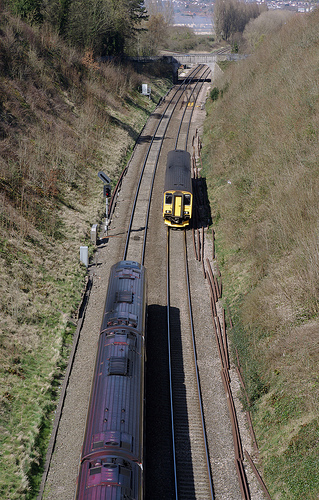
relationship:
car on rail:
[162, 149, 194, 230] [40, 63, 215, 497]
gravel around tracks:
[199, 246, 214, 274] [169, 223, 202, 322]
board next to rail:
[200, 228, 233, 305] [40, 63, 215, 497]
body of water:
[174, 8, 204, 29] [192, 8, 221, 29]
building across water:
[173, 10, 290, 69] [192, 8, 221, 29]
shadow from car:
[207, 185, 218, 217] [162, 149, 194, 230]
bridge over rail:
[169, 12, 275, 99] [40, 63, 215, 497]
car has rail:
[162, 149, 194, 230] [40, 63, 215, 497]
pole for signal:
[90, 180, 119, 242] [101, 176, 122, 243]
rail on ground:
[134, 258, 203, 393] [177, 236, 198, 343]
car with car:
[162, 149, 194, 230] [77, 326, 158, 461]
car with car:
[162, 149, 194, 230] [68, 452, 146, 495]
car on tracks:
[162, 149, 194, 230] [33, 61, 240, 497]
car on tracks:
[75, 260, 146, 497] [33, 61, 240, 497]